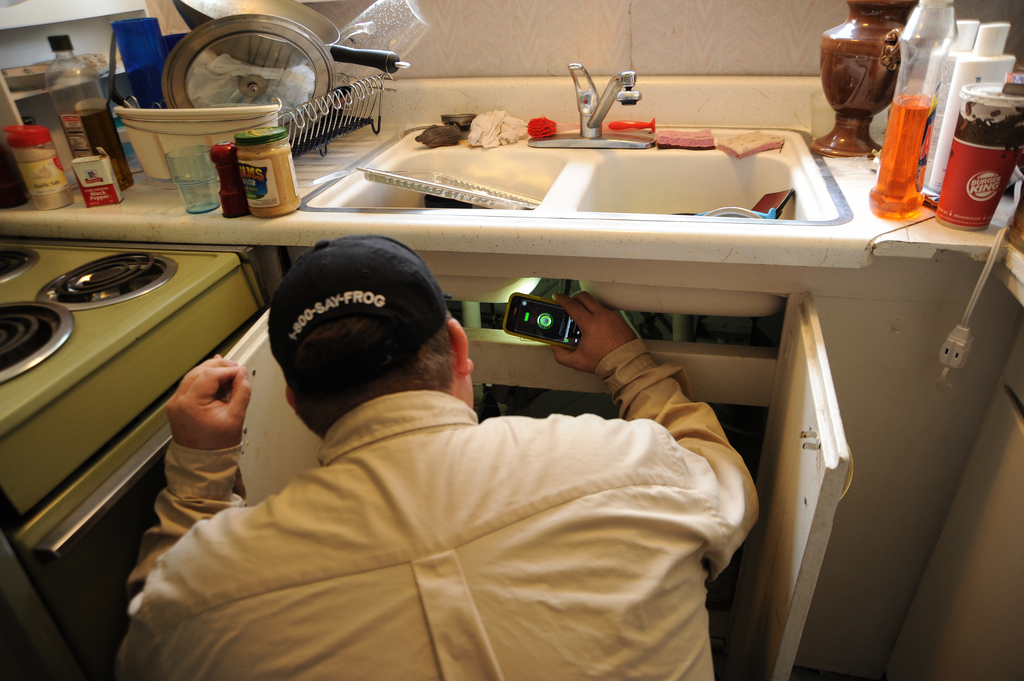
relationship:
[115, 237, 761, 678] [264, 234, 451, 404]
man wearing cap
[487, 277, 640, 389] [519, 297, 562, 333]
phone has lights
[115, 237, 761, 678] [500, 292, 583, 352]
man holding phone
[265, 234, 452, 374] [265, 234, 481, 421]
cap on head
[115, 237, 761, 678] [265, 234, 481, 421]
man has head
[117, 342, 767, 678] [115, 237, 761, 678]
white shirt on man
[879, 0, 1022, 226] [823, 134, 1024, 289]
items on counter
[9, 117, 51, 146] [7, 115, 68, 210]
red lid on spice container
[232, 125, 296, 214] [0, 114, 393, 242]
jar on counter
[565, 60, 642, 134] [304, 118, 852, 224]
faucet on sink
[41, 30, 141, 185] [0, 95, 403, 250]
bottle on counter